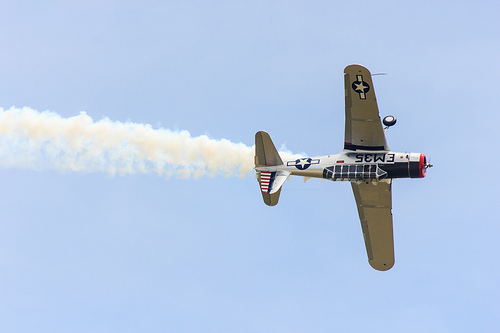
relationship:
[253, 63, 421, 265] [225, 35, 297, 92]
airplane in air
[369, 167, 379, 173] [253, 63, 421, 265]
window on airplane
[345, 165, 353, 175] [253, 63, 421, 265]
window on airplane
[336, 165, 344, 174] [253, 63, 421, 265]
window on airplane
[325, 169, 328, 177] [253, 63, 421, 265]
window on airplane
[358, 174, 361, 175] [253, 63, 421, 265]
window in airplane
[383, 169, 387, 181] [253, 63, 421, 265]
cockpit of airplane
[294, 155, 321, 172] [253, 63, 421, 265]
star on airplane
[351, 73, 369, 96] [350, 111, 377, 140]
star on wing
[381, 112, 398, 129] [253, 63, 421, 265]
wheel on airplane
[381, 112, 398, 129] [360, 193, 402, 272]
wheel above wing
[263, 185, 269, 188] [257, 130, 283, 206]
stripe on tail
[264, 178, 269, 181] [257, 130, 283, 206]
stripe on tail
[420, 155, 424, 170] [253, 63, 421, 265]
paint on airplane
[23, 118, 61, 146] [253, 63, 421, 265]
smoke from airplane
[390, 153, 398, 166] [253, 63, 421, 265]
letter on airplane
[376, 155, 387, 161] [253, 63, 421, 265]
letter on airplane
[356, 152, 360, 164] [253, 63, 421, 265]
number on airplane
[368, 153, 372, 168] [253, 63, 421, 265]
number on airplane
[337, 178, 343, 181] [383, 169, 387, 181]
metal on cockpit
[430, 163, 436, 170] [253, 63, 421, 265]
nose of airplane